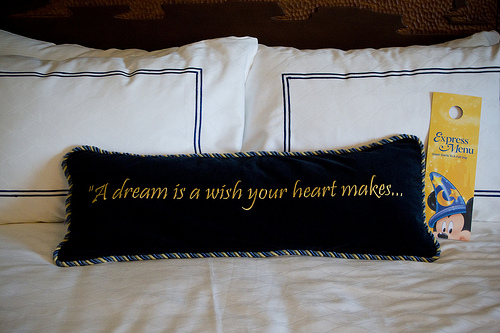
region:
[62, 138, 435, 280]
Blue pillow on the bed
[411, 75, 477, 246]
Tag on a bed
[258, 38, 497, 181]
white pillow on the bed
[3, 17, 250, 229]
white pillow on the bed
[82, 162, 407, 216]
Words on a pillow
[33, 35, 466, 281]
Three pillows and a tag on a bed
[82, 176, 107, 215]
Golden letter on a blue pillow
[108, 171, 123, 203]
Golden letter on a blue pillow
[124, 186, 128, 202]
Golden letter on a blue pillow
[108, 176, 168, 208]
Golden letter on a blue pillow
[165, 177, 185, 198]
Golden letter on a blue pillow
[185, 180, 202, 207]
Golden letter on a blue pillow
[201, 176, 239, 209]
Golden letter on a blue pillow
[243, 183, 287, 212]
Golden letter on a blue pillow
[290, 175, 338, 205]
Golden letter on a blue pillow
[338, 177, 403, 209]
Golden letter on a blue pillow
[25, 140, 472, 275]
long pillow on the bed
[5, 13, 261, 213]
pillow on the bed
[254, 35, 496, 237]
pillow on the bed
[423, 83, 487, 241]
card from hotel for customers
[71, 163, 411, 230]
phrase on the pillow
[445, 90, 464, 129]
hole to hang card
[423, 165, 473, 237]
cartoon image on card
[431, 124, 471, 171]
phrase on the card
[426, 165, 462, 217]
hat on cartoon character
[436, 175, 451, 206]
print on the hat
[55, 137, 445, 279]
long black pillow with gold lettering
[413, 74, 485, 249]
yellow bag with mickey mouse on it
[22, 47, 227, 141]
white pillow and blue trim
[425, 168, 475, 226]
purple wizard hat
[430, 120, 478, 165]
blue letters on yellow bag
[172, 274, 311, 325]
white bed blanket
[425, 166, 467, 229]
purple hat with gold stars and moons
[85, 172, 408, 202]
letters written in gold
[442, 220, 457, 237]
two eyes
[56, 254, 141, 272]
blue trim with gold threads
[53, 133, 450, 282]
Blue and gold pillow on a bed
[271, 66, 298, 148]
Blue lines on a white pillow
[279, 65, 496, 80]
Blue lines on a white pillow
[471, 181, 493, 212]
Blue lines on a white pillow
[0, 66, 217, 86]
Blue lines on a white pillow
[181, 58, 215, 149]
Blue lines on a white pillow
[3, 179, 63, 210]
Blue lines on a white pillow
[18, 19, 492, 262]
Pillows on a bed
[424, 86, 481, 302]
Yellow and blue door hanger on the bed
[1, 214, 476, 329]
White comforter on a bes